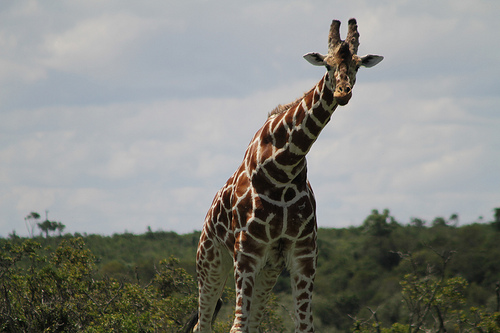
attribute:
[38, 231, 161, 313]
green leaves — lush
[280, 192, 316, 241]
spot — brown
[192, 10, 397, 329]
giraffe — white , Brown 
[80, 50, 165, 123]
sky — white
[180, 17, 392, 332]
giraffe — adult, large, brown, white, WITH LARGE SPOTS, WITH BROWN SPOTS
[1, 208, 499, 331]
grassland — grass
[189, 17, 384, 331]
large giraffe — adult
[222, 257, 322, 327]
legs — giraffe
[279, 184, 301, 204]
spot — brown 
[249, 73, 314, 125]
mane — brown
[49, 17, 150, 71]
cloud — greyish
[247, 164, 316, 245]
spots — brown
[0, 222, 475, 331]
area — vast, grassy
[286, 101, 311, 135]
spot — brown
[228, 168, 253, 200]
spot — brown